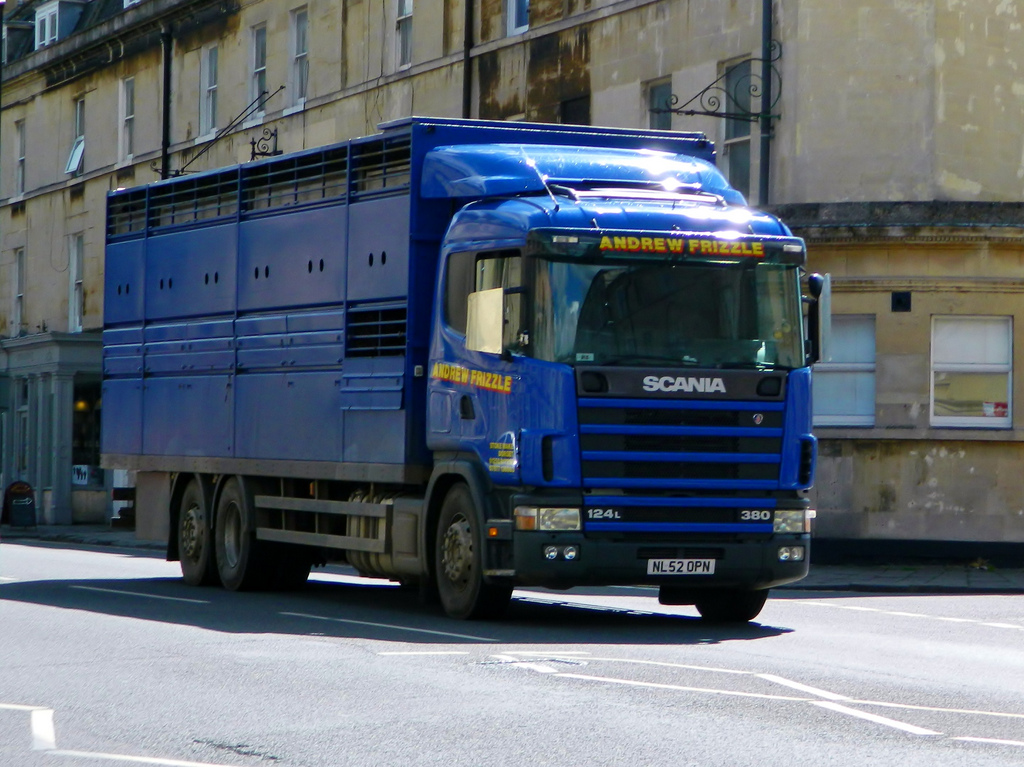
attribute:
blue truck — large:
[88, 109, 834, 628]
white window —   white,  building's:
[812, 305, 888, 432]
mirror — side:
[460, 288, 524, 359]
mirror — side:
[795, 265, 837, 374]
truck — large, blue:
[102, 111, 839, 627]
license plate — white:
[642, 557, 722, 573]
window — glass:
[808, 310, 879, 435]